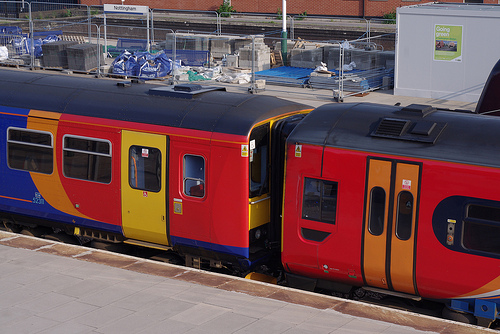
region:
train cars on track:
[7, 62, 492, 303]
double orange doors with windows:
[347, 106, 447, 309]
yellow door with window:
[94, 119, 185, 273]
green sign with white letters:
[427, 17, 488, 74]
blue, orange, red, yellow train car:
[4, 94, 273, 255]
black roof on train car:
[19, 61, 272, 254]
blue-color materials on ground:
[247, 60, 338, 94]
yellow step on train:
[115, 204, 198, 269]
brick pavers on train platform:
[39, 259, 277, 331]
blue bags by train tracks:
[97, 44, 188, 81]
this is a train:
[46, 90, 395, 248]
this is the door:
[368, 166, 410, 298]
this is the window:
[303, 179, 333, 219]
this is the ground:
[12, 255, 133, 331]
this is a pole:
[281, 5, 290, 41]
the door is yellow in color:
[119, 141, 165, 233]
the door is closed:
[122, 138, 160, 213]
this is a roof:
[308, 4, 362, 14]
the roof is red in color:
[312, 2, 352, 14]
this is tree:
[218, 4, 229, 13]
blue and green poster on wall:
[422, 15, 477, 79]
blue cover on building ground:
[240, 53, 322, 85]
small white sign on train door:
[396, 175, 425, 190]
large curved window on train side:
[291, 167, 353, 261]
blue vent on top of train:
[138, 54, 259, 106]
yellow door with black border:
[94, 120, 189, 261]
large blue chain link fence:
[302, 43, 404, 95]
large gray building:
[389, 7, 484, 109]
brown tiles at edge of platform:
[98, 253, 228, 295]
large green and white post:
[266, 9, 306, 80]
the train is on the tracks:
[21, 61, 492, 323]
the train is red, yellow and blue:
[25, 47, 452, 292]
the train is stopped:
[9, 47, 467, 286]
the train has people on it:
[29, 62, 473, 297]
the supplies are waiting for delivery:
[79, 22, 394, 110]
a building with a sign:
[391, 6, 493, 119]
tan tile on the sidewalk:
[25, 248, 161, 332]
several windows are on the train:
[5, 119, 487, 266]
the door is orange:
[365, 149, 413, 294]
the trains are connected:
[31, 55, 470, 293]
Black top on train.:
[100, 59, 404, 146]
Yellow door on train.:
[351, 199, 421, 274]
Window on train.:
[293, 173, 371, 328]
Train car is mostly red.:
[306, 137, 453, 299]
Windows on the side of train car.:
[5, 122, 218, 242]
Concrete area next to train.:
[43, 268, 217, 330]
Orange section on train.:
[14, 115, 70, 242]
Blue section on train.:
[8, 107, 88, 267]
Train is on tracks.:
[32, 131, 362, 326]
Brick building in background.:
[301, 7, 405, 38]